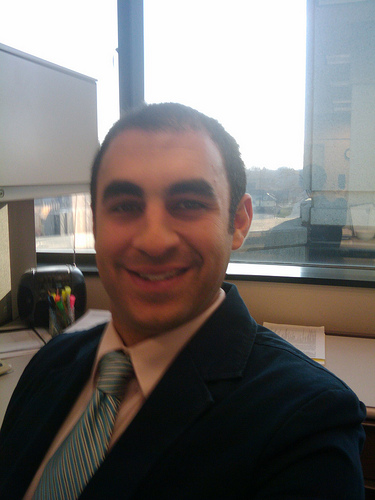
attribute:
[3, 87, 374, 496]
man — smiling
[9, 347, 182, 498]
tie — blue, striped, blue white, gold, grey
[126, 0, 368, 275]
window — large, clear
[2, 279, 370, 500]
jacket — black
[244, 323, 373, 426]
cabinet — white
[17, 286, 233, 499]
shirt — white, pale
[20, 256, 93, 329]
radio — small, black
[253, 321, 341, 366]
paperwork — white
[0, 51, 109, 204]
cabinet — overhead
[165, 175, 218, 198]
eyebrow — thick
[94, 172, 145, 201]
eyebrow — thick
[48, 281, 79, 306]
highlighters — yellow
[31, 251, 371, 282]
ledge — empty, dark